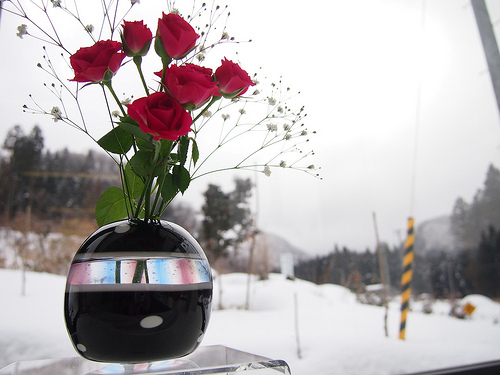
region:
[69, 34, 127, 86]
a red rose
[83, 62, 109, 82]
a red rose petal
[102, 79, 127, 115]
a green flower stem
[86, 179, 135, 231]
a green rose leaf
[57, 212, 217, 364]
a black and silver vase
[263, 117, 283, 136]
a small white flower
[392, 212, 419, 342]
a yellow and black pole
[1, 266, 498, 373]
white snow on the ground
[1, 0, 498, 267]
a gray sky overhead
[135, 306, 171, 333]
light shining on the vase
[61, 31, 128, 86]
a red rose flower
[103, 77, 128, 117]
the stem of a rose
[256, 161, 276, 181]
a small white flower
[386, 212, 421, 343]
a black and yellow pole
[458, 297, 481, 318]
a yellow sign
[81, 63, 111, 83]
the petal of a flower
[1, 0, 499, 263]
a cloudy gray sky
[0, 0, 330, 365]
a beautiful flower vase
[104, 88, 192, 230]
a pink rose in the vase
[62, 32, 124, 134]
a pink rose in the vase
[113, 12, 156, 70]
a pink rose in the vase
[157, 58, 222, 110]
a pink rose in the vase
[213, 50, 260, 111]
a pink rose in the vase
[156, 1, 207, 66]
a pink rose in the vase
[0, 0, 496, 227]
the sky is clear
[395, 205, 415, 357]
yellow and black stripped post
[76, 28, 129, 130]
red and green rose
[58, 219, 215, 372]
black and silver vase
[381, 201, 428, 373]
yellow and black pole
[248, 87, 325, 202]
white and green babys breath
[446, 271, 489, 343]
a yellow road sign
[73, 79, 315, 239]
red roses with baby breath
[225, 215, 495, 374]
white snow and green trees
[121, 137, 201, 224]
green leaves on a rose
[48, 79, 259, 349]
bunch of roses in a vase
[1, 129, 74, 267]
green trees and a hill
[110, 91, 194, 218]
red rose with green stems and leaves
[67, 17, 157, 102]
two red roses with a green stem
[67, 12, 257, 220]
five red roses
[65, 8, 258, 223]
red flowers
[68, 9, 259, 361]
red roses in a black round vase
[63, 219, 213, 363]
round black vase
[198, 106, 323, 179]
tiny white flowers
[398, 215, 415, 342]
yellow and gray striped pole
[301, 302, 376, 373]
snow on the ground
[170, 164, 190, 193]
green leaf